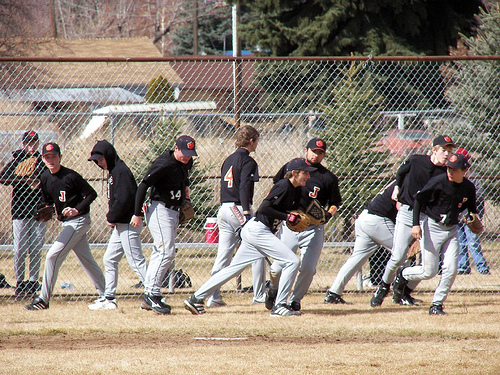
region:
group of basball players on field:
[9, 122, 499, 317]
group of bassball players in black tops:
[3, 125, 485, 227]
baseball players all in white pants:
[22, 206, 475, 301]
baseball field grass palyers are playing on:
[1, 293, 498, 373]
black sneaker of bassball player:
[143, 294, 173, 314]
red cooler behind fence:
[204, 217, 216, 244]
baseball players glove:
[468, 214, 483, 234]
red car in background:
[365, 129, 437, 156]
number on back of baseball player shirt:
[225, 167, 234, 188]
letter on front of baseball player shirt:
[58, 191, 65, 202]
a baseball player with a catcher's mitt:
[3, 130, 52, 297]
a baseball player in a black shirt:
[25, 141, 104, 316]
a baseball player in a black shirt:
[127, 135, 197, 311]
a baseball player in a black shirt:
[196, 126, 266, 306]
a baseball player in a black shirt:
[184, 157, 319, 319]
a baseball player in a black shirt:
[272, 140, 343, 310]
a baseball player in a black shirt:
[395, 153, 482, 314]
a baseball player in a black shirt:
[371, 133, 454, 305]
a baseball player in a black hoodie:
[86, 139, 147, 307]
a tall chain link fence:
[1, 54, 498, 303]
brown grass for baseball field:
[88, 349, 292, 368]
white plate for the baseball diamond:
[192, 326, 256, 346]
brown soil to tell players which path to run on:
[8, 332, 181, 346]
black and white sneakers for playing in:
[179, 293, 210, 307]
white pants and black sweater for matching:
[33, 169, 102, 295]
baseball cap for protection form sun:
[304, 136, 329, 153]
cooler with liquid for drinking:
[202, 212, 218, 241]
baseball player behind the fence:
[3, 128, 43, 292]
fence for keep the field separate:
[0, 58, 497, 128]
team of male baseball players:
[2, 132, 482, 312]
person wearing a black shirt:
[43, 168, 93, 221]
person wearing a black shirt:
[155, 157, 192, 239]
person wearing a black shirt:
[216, 152, 253, 211]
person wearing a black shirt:
[261, 182, 290, 239]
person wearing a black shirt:
[308, 167, 341, 219]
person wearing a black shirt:
[371, 175, 394, 236]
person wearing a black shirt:
[403, 156, 422, 214]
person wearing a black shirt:
[426, 175, 481, 233]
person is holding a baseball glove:
[463, 202, 487, 240]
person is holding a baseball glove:
[278, 206, 312, 231]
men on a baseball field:
[51, 121, 493, 366]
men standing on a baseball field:
[0, 66, 481, 373]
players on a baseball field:
[92, 113, 482, 335]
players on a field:
[82, 118, 460, 358]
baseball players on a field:
[68, 143, 425, 346]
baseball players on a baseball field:
[41, 104, 432, 372]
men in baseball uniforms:
[82, 103, 414, 295]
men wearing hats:
[62, 152, 364, 325]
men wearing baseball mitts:
[219, 167, 496, 307]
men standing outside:
[37, 91, 427, 373]